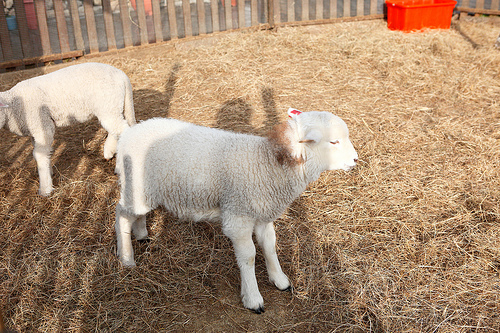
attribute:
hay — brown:
[131, 219, 312, 331]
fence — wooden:
[0, 0, 499, 74]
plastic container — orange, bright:
[385, 1, 457, 32]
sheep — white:
[7, 47, 145, 195]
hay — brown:
[13, 21, 498, 310]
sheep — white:
[3, 62, 361, 316]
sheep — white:
[1, 60, 137, 196]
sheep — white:
[115, 90, 364, 263]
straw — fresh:
[323, 9, 498, 168]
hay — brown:
[0, 12, 499, 332]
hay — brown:
[194, 54, 416, 91]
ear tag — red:
[284, 108, 306, 122]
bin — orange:
[374, 2, 485, 55]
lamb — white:
[105, 100, 370, 321]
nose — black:
[350, 155, 363, 163]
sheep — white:
[107, 100, 367, 314]